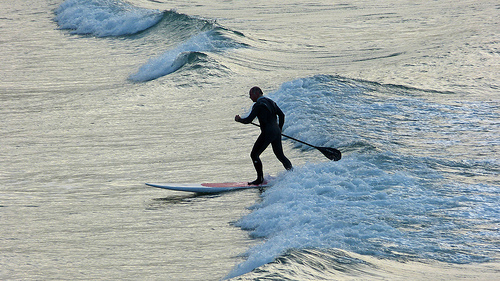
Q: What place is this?
A: It is an ocean.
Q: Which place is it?
A: It is an ocean.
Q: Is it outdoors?
A: Yes, it is outdoors.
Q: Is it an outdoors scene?
A: Yes, it is outdoors.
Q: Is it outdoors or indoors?
A: It is outdoors.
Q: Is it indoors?
A: No, it is outdoors.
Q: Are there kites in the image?
A: No, there are no kites.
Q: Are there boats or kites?
A: No, there are no kites or boats.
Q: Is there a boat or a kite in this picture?
A: No, there are no kites or boats.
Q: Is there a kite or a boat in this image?
A: No, there are no kites or boats.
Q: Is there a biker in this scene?
A: No, there are no bikers.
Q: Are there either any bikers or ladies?
A: No, there are no bikers or ladies.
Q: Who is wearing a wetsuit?
A: The man is wearing a wetsuit.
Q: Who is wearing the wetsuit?
A: The man is wearing a wetsuit.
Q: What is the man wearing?
A: The man is wearing a wetsuit.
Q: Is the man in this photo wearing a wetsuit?
A: Yes, the man is wearing a wetsuit.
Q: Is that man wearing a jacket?
A: No, the man is wearing a wetsuit.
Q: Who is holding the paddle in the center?
A: The man is holding the paddle.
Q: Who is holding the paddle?
A: The man is holding the paddle.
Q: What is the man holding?
A: The man is holding the paddle.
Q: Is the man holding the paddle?
A: Yes, the man is holding the paddle.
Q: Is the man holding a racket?
A: No, the man is holding the paddle.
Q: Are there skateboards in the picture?
A: No, there are no skateboards.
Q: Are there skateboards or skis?
A: No, there are no skateboards or skis.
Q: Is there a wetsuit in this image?
A: Yes, there is a wetsuit.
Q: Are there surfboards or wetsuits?
A: Yes, there is a wetsuit.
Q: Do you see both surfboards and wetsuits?
A: Yes, there are both a wetsuit and a surfboard.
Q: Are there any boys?
A: No, there are no boys.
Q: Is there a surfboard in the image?
A: Yes, there is a surfboard.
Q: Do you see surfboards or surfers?
A: Yes, there is a surfboard.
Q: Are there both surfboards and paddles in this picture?
A: Yes, there are both a surfboard and a paddle.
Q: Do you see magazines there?
A: No, there are no magazines.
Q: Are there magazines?
A: No, there are no magazines.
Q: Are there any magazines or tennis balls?
A: No, there are no magazines or tennis balls.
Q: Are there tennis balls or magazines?
A: No, there are no magazines or tennis balls.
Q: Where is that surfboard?
A: The surfboard is on the ocean.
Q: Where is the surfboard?
A: The surfboard is on the ocean.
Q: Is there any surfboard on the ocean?
A: Yes, there is a surfboard on the ocean.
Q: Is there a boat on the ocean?
A: No, there is a surfboard on the ocean.